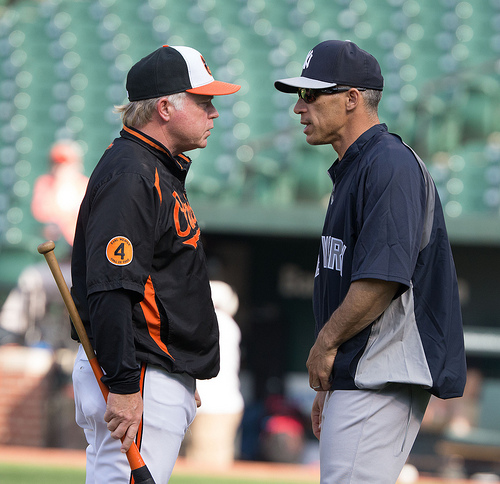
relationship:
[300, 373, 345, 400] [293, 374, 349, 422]
ring on finger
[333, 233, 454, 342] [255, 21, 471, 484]
arm of people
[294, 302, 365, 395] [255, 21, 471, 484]
hand of people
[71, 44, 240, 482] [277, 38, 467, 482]
baseball coach arguing with baseball player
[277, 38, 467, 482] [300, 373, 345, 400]
baseball player wearing a ring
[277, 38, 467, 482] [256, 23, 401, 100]
baseball player wearing a cap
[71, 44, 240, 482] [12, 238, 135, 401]
baseball coach holding bat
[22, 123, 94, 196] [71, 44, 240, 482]
spectacle created by baseball coach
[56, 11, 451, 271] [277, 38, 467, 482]
men talking to baseball player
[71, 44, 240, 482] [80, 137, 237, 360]
baseball coach wearing a jacket